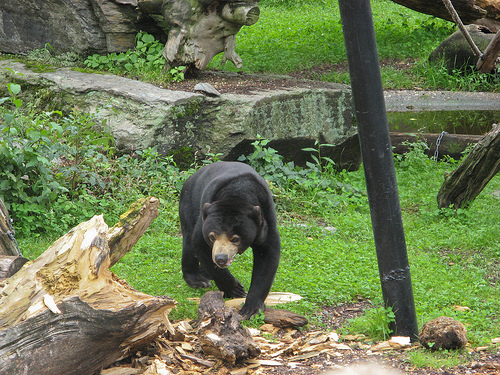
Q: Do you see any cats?
A: No, there are no cats.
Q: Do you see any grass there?
A: Yes, there is grass.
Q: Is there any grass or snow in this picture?
A: Yes, there is grass.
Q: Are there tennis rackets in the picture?
A: No, there are no tennis rackets.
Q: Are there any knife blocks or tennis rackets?
A: No, there are no tennis rackets or knife blocks.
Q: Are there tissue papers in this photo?
A: No, there are no tissue papers.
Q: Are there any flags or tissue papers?
A: No, there are no tissue papers or flags.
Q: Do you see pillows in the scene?
A: No, there are no pillows.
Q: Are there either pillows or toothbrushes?
A: No, there are no pillows or toothbrushes.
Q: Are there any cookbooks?
A: No, there are no cookbooks.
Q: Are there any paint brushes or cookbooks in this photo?
A: No, there are no cookbooks or paint brushes.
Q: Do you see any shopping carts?
A: No, there are no shopping carts.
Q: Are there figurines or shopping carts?
A: No, there are no shopping carts or figurines.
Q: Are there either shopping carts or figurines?
A: No, there are no shopping carts or figurines.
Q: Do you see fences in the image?
A: No, there are no fences.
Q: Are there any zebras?
A: No, there are no zebras.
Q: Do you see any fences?
A: No, there are no fences.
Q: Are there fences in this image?
A: No, there are no fences.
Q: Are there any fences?
A: No, there are no fences.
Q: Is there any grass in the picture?
A: Yes, there is grass.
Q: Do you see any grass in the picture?
A: Yes, there is grass.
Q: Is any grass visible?
A: Yes, there is grass.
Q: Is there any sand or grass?
A: Yes, there is grass.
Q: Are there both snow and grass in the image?
A: No, there is grass but no snow.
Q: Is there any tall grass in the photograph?
A: Yes, there is tall grass.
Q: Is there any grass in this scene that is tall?
A: Yes, there is grass that is tall.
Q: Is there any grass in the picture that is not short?
A: Yes, there is tall grass.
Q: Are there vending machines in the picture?
A: No, there are no vending machines.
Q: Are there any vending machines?
A: No, there are no vending machines.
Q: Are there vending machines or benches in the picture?
A: No, there are no vending machines or benches.